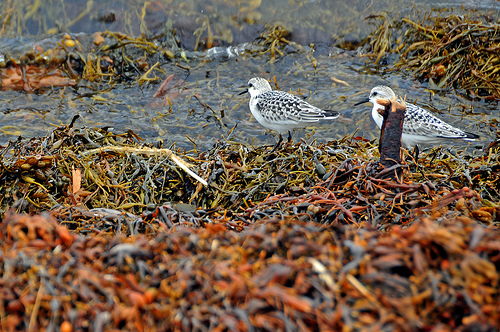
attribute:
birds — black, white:
[243, 70, 497, 155]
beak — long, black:
[232, 79, 250, 96]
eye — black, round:
[244, 81, 254, 89]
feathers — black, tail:
[454, 124, 483, 146]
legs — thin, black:
[277, 131, 296, 144]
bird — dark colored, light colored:
[243, 69, 343, 149]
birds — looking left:
[241, 69, 484, 172]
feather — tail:
[456, 123, 486, 156]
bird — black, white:
[243, 72, 348, 151]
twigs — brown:
[40, 139, 270, 264]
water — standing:
[33, 84, 247, 158]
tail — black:
[314, 108, 344, 118]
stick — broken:
[374, 96, 411, 171]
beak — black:
[343, 93, 369, 110]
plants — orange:
[151, 214, 464, 330]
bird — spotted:
[347, 77, 479, 169]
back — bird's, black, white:
[283, 88, 307, 108]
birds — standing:
[248, 65, 459, 172]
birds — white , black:
[219, 61, 480, 143]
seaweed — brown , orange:
[144, 207, 449, 300]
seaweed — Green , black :
[80, 151, 407, 198]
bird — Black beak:
[237, 70, 477, 154]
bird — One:
[357, 71, 475, 175]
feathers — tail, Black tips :
[463, 121, 484, 151]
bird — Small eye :
[226, 71, 346, 144]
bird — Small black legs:
[235, 75, 358, 161]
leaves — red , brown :
[139, 235, 449, 317]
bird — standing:
[218, 56, 484, 158]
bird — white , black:
[238, 72, 467, 162]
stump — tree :
[0, 35, 190, 93]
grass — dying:
[43, 156, 313, 192]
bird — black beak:
[233, 66, 463, 152]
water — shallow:
[98, 85, 214, 137]